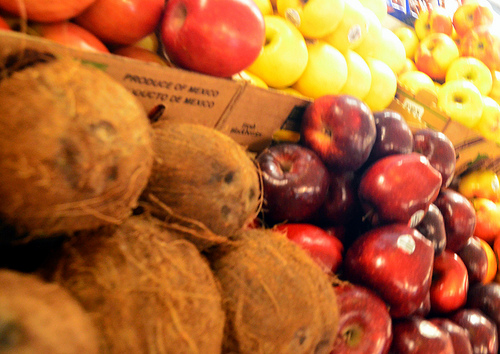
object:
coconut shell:
[156, 121, 278, 248]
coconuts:
[7, 58, 344, 352]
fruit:
[11, 1, 500, 354]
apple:
[256, 95, 495, 351]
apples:
[1, 0, 262, 76]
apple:
[455, 5, 495, 39]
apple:
[414, 11, 452, 39]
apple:
[416, 31, 458, 86]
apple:
[459, 28, 499, 71]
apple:
[443, 56, 492, 94]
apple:
[336, 283, 391, 352]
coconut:
[2, 52, 162, 252]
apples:
[257, 0, 417, 109]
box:
[229, 86, 314, 149]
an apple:
[302, 101, 384, 165]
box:
[0, 25, 500, 197]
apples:
[445, 55, 496, 103]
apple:
[163, 0, 265, 73]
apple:
[78, 2, 163, 42]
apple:
[2, 2, 94, 20]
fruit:
[214, 88, 494, 352]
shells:
[211, 225, 336, 352]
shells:
[58, 214, 226, 351]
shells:
[0, 269, 100, 351]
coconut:
[82, 68, 317, 262]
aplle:
[161, 0, 264, 79]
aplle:
[255, 142, 331, 222]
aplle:
[357, 147, 444, 228]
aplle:
[342, 213, 439, 318]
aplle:
[397, 314, 450, 352]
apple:
[394, 194, 453, 255]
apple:
[410, 115, 454, 179]